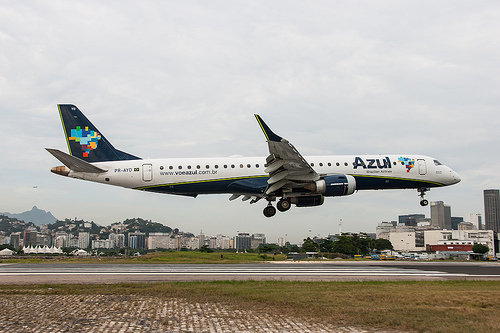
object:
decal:
[66, 124, 100, 157]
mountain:
[20, 206, 59, 223]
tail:
[55, 103, 139, 160]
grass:
[230, 277, 497, 330]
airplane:
[44, 99, 466, 219]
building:
[386, 225, 496, 260]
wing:
[254, 114, 322, 183]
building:
[250, 233, 266, 251]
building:
[127, 230, 146, 251]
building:
[483, 188, 500, 231]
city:
[1, 187, 499, 261]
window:
[160, 166, 165, 170]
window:
[169, 165, 174, 169]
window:
[178, 165, 183, 169]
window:
[187, 165, 192, 170]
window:
[196, 165, 200, 170]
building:
[427, 239, 495, 259]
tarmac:
[0, 255, 499, 286]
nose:
[452, 172, 461, 184]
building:
[426, 200, 455, 230]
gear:
[276, 188, 296, 212]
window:
[215, 164, 219, 168]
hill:
[107, 217, 183, 232]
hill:
[40, 216, 108, 233]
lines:
[0, 272, 500, 277]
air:
[0, 0, 500, 241]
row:
[155, 160, 346, 169]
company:
[353, 156, 392, 168]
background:
[0, 0, 500, 260]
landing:
[1, 253, 499, 286]